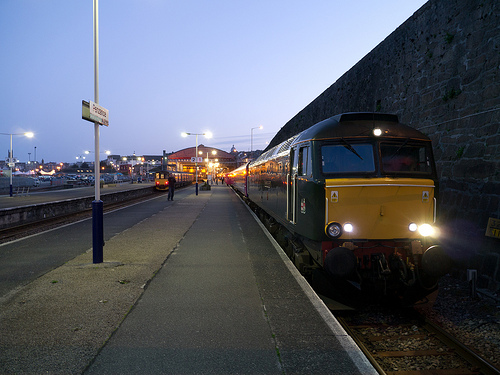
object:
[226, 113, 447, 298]
train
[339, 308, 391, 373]
tracks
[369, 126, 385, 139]
light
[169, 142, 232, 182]
station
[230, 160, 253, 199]
cars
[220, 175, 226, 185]
people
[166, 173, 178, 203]
man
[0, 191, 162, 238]
tracks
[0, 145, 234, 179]
city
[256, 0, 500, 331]
wall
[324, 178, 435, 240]
yellow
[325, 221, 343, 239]
headlight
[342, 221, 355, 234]
light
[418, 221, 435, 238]
headlight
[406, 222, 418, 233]
light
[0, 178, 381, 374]
sidewalk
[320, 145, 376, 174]
windows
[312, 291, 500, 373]
gravel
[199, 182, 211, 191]
grass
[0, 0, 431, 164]
sky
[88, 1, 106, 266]
pole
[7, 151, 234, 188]
background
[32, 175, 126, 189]
lot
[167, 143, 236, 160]
roof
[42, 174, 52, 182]
cars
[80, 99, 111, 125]
white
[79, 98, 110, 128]
sign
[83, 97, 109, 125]
blue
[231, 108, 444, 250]
black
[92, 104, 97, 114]
letters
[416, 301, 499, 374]
train tracks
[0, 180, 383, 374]
platform